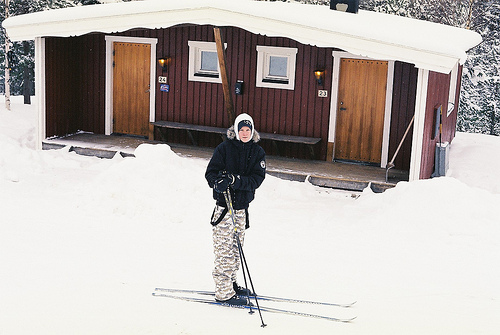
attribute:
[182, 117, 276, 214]
winter jacket — winter jacket, fur lined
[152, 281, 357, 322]
skis —  Two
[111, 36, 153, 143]
door — brown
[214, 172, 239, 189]
hands — gloved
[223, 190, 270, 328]
ski poles —  Two, for ski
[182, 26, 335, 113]
windows — square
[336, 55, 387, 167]
door — wood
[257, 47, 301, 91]
window —  Two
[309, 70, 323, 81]
light — black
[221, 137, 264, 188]
jacket — black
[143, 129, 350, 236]
coat — black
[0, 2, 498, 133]
trees — snow covered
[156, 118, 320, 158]
bench — flat 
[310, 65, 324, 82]
light — glowing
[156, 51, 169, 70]
light — glowing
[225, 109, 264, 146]
hood — fur lined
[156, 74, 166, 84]
sign — white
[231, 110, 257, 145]
hood — white